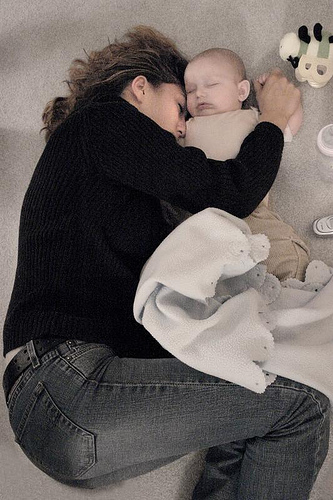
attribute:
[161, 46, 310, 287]
baby — her  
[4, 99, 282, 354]
sweater — black 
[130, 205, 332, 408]
blanket — baby 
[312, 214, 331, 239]
shoe — part , baby white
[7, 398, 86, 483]
pocket — back 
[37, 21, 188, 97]
hair — dark brown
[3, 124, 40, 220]
shadow — part , shade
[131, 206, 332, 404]
cloth — baby white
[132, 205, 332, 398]
towel — edge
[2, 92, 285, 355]
shirt — black 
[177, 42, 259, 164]
baby — peaceful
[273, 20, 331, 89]
toy — baby 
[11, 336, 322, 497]
jeans — sexy 